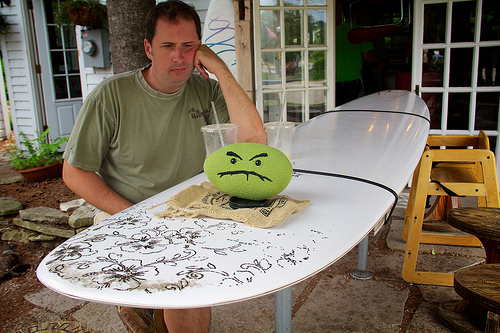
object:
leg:
[160, 307, 213, 333]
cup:
[261, 119, 297, 163]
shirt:
[60, 64, 232, 204]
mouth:
[168, 66, 190, 75]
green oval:
[200, 141, 295, 202]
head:
[140, 0, 203, 84]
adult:
[59, 0, 268, 332]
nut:
[201, 141, 294, 211]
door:
[249, 0, 337, 125]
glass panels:
[281, 47, 305, 87]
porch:
[0, 152, 499, 333]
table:
[33, 89, 432, 333]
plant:
[5, 127, 69, 169]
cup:
[198, 120, 238, 158]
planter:
[17, 158, 70, 183]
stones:
[16, 204, 70, 226]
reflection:
[257, 0, 327, 124]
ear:
[140, 37, 152, 61]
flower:
[90, 257, 160, 293]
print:
[103, 227, 171, 256]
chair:
[398, 130, 499, 289]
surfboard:
[200, 0, 238, 81]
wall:
[191, 0, 213, 38]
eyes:
[160, 43, 174, 50]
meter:
[79, 26, 112, 70]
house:
[0, 0, 499, 190]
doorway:
[0, 152, 82, 211]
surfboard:
[34, 88, 432, 310]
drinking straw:
[209, 100, 225, 148]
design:
[202, 10, 237, 56]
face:
[202, 141, 294, 202]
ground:
[0, 158, 499, 333]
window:
[306, 89, 328, 122]